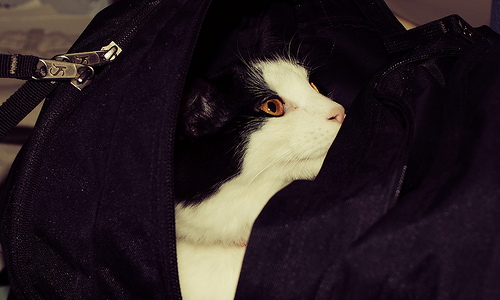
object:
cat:
[171, 37, 346, 299]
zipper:
[0, 0, 156, 300]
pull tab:
[55, 41, 123, 65]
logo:
[50, 62, 67, 76]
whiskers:
[240, 136, 321, 194]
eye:
[259, 94, 286, 118]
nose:
[326, 104, 345, 124]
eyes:
[311, 82, 319, 92]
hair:
[186, 61, 297, 209]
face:
[236, 56, 346, 181]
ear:
[185, 85, 226, 136]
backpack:
[0, 0, 499, 300]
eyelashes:
[232, 34, 322, 87]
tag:
[31, 58, 96, 91]